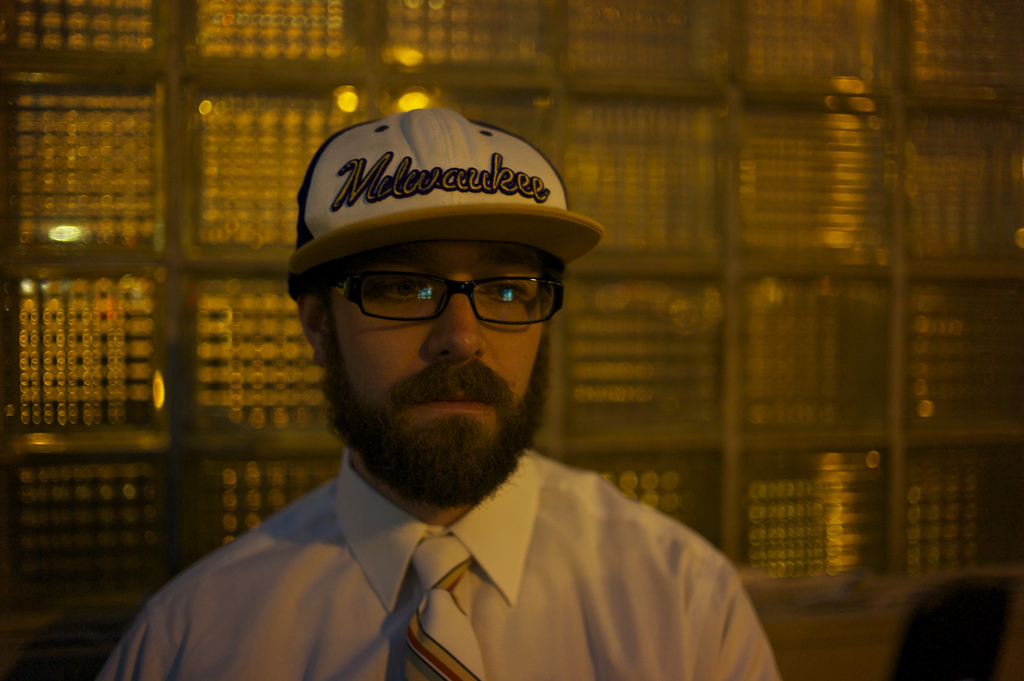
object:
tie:
[410, 527, 490, 681]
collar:
[332, 446, 538, 613]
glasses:
[318, 272, 565, 323]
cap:
[276, 106, 608, 269]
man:
[102, 106, 776, 679]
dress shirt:
[95, 451, 790, 679]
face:
[332, 262, 545, 401]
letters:
[328, 149, 552, 210]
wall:
[5, 5, 1024, 681]